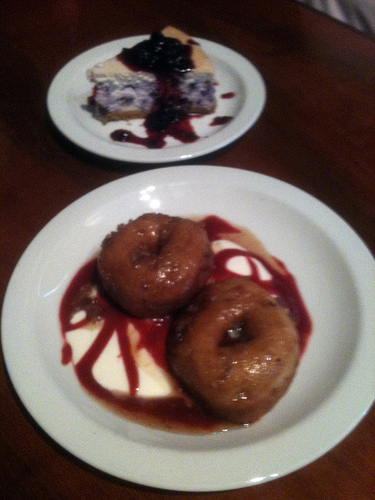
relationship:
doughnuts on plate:
[164, 277, 304, 430] [3, 164, 375, 495]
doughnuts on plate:
[93, 210, 215, 324] [3, 164, 375, 495]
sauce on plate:
[55, 210, 320, 435] [3, 164, 375, 495]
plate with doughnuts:
[3, 164, 375, 495] [164, 277, 304, 430]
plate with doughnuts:
[3, 164, 375, 495] [93, 210, 215, 324]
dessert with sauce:
[77, 26, 218, 90] [120, 29, 193, 77]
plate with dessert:
[43, 26, 271, 167] [77, 26, 218, 90]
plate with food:
[43, 26, 271, 167] [86, 73, 224, 128]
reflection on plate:
[132, 181, 166, 217] [3, 164, 375, 495]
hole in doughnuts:
[215, 317, 249, 349] [164, 277, 304, 430]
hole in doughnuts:
[146, 236, 165, 259] [93, 210, 215, 324]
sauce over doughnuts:
[55, 210, 320, 435] [164, 277, 304, 430]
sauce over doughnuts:
[55, 210, 320, 435] [93, 210, 215, 324]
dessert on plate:
[77, 26, 218, 90] [43, 26, 271, 167]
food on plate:
[86, 73, 224, 128] [43, 26, 271, 167]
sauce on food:
[120, 29, 193, 77] [86, 73, 224, 128]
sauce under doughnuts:
[55, 210, 320, 435] [164, 277, 304, 430]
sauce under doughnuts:
[55, 210, 320, 435] [93, 210, 215, 324]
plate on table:
[3, 164, 375, 495] [1, 1, 375, 500]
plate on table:
[43, 26, 271, 167] [1, 1, 375, 500]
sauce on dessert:
[120, 29, 193, 77] [77, 26, 218, 90]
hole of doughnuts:
[215, 317, 249, 349] [164, 277, 304, 430]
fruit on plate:
[143, 106, 191, 131] [43, 26, 271, 167]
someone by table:
[302, 2, 373, 42] [1, 1, 375, 500]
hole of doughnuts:
[146, 236, 165, 259] [164, 277, 304, 430]